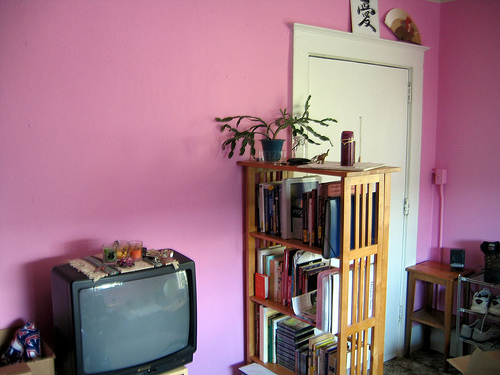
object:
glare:
[89, 276, 190, 318]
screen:
[79, 268, 190, 372]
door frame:
[291, 22, 430, 359]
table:
[401, 256, 475, 365]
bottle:
[338, 129, 357, 165]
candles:
[101, 234, 146, 269]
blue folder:
[322, 193, 352, 259]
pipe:
[438, 186, 445, 265]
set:
[51, 247, 198, 374]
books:
[253, 175, 276, 237]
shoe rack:
[451, 270, 500, 373]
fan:
[381, 6, 426, 43]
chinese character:
[356, 0, 375, 37]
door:
[308, 55, 410, 371]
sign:
[349, 0, 377, 35]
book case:
[236, 153, 397, 375]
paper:
[350, 1, 382, 41]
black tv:
[52, 245, 195, 371]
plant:
[213, 93, 338, 161]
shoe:
[479, 240, 499, 283]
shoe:
[459, 318, 482, 340]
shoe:
[471, 321, 497, 343]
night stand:
[397, 247, 483, 371]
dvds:
[277, 317, 306, 369]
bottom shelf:
[243, 296, 382, 371]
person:
[251, 132, 294, 161]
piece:
[4, 316, 47, 363]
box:
[0, 359, 60, 367]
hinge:
[408, 80, 412, 102]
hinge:
[403, 199, 408, 221]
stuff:
[4, 317, 42, 364]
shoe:
[470, 287, 492, 314]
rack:
[455, 267, 500, 356]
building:
[242, 159, 405, 370]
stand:
[402, 258, 474, 365]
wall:
[4, 2, 434, 372]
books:
[260, 307, 274, 362]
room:
[0, 12, 500, 375]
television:
[48, 246, 197, 373]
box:
[167, 249, 299, 359]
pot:
[261, 138, 287, 160]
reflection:
[74, 282, 189, 375]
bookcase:
[240, 154, 395, 373]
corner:
[432, 4, 443, 352]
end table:
[403, 258, 482, 371]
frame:
[289, 20, 427, 366]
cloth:
[69, 247, 177, 281]